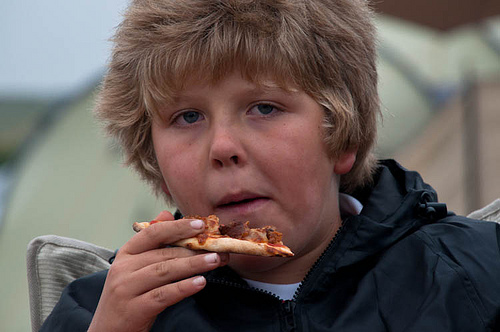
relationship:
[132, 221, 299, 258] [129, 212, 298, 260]
crust of pizza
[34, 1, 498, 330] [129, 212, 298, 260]
boy eating pizza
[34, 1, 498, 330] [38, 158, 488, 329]
boy wearing windbreaker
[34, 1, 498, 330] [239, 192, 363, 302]
boy wearing shirt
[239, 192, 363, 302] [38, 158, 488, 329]
shirt under windbreaker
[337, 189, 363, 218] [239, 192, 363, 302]
collar of a shirt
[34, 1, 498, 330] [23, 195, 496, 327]
boy sitting on a chair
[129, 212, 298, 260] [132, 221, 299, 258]
pizza has a crust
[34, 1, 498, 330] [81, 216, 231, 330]
boy has hand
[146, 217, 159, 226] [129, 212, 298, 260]
pepperoni on pizza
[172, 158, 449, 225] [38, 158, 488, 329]
hood on windbreaker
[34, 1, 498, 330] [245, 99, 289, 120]
boy with eye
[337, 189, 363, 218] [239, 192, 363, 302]
collar of shirt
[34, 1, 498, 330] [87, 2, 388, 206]
boy with hair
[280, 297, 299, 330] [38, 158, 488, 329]
pull on a windbreaker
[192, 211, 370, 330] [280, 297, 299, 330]
zipper has a pull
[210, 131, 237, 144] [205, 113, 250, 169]
freckles on nose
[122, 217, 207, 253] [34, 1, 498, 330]
finger of boy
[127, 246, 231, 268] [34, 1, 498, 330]
finger of boy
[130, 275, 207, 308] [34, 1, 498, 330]
finger of boy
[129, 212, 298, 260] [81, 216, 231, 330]
pizza in hand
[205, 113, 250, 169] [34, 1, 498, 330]
nose of boy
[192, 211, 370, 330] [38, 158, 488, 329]
zipper on windbreaker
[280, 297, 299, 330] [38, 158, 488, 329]
pull on windbreaker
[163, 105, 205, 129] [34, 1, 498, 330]
eye of boy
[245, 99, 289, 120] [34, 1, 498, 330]
eye of boy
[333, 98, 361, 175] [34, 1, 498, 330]
ear of boy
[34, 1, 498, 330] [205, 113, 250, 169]
boy has a nose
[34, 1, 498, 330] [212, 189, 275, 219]
boy has a mouth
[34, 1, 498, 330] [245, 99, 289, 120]
boy has eye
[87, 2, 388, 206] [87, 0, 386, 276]
hair on head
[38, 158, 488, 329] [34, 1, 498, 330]
windbreaker on boy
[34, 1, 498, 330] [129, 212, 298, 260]
boy has pizza